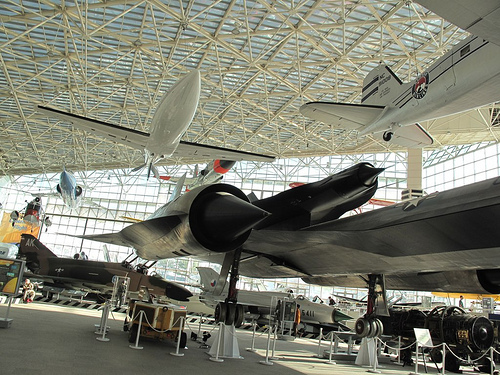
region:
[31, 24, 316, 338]
a white plane is hovering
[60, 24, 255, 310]
a white plane is hovering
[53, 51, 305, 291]
a white plane is hovering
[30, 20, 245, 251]
a white plane is hovering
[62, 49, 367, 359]
a white plane is hovering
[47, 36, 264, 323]
a white plane is hovering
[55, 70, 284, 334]
a white plane is hovering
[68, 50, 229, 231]
a white plane is hovering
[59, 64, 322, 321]
a white plane is hovering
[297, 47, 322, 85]
roof of a building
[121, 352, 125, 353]
part of a floor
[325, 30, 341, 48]
rail of a roof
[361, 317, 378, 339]
wheel of a plane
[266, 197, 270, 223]
tip of a jet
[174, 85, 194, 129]
bottom of a plane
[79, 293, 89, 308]
black and white surface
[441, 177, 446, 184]
part of a window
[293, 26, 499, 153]
A plane hanging from the ceiling.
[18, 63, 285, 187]
The aircraft is on display.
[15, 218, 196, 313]
Military aircraft on show.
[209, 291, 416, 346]
Wheels on aircraft are down.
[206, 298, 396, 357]
The wheels are round.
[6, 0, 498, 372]
Various forms of aircraft.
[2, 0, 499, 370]
Aircraft covering different periods in time.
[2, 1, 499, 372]
Aircraft spanning the history of air travel.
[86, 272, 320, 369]
Barriers to keep people out.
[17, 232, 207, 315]
The aircraft is army green.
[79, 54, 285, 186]
a white plane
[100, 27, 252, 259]
a white plane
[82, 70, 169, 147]
a white plane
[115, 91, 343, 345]
a white plane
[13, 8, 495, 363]
An aircraft exhibit is pictured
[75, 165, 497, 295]
This is an SR-71 Blackbird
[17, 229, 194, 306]
This plane is an F-4 Phantom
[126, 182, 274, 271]
This is a jet engine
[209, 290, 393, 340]
The jet's landing gears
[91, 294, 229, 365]
Stanchions surround the exhibits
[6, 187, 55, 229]
This is a helicopter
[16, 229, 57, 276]
The jet's tail section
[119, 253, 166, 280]
This is the jet's cockpit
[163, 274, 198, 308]
The jet's nose section